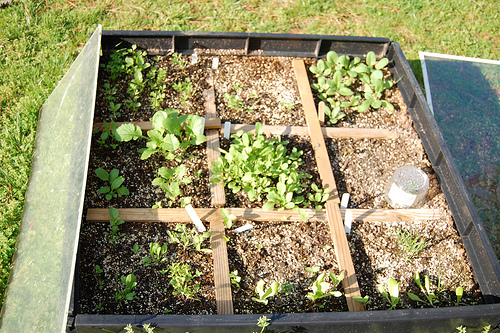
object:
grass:
[0, 0, 75, 62]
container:
[385, 162, 430, 209]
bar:
[208, 215, 233, 317]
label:
[185, 203, 206, 233]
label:
[344, 208, 354, 234]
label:
[340, 193, 350, 209]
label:
[221, 121, 231, 141]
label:
[211, 55, 219, 71]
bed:
[0, 23, 500, 333]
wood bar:
[199, 52, 222, 206]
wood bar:
[94, 122, 397, 139]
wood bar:
[90, 208, 439, 219]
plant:
[113, 108, 209, 159]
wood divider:
[292, 54, 364, 308]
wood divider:
[195, 51, 237, 314]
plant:
[11, 118, 27, 200]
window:
[415, 50, 499, 246]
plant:
[210, 122, 330, 222]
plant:
[95, 168, 130, 200]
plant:
[311, 49, 402, 125]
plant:
[394, 225, 441, 262]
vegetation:
[107, 274, 144, 302]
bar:
[293, 55, 364, 310]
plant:
[252, 272, 292, 305]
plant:
[101, 45, 194, 122]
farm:
[88, 40, 472, 311]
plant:
[307, 274, 340, 302]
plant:
[376, 276, 403, 310]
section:
[74, 217, 214, 313]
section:
[225, 217, 346, 317]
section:
[343, 215, 483, 305]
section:
[88, 125, 210, 208]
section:
[221, 130, 328, 208]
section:
[325, 134, 451, 211]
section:
[93, 47, 207, 117]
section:
[212, 57, 305, 126]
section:
[306, 57, 414, 132]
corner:
[305, 37, 415, 133]